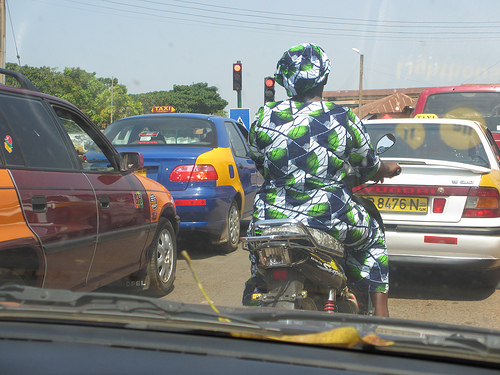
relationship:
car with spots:
[63, 93, 299, 271] [178, 126, 254, 205]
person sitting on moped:
[239, 42, 402, 318] [234, 123, 428, 321]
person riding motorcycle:
[239, 42, 402, 318] [223, 119, 430, 318]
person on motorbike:
[239, 42, 402, 318] [232, 130, 409, 326]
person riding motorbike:
[239, 42, 402, 318] [235, 123, 435, 323]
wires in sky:
[85, 2, 497, 49] [3, 3, 495, 126]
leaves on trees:
[51, 69, 234, 129] [0, 49, 239, 150]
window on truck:
[423, 93, 495, 133] [407, 76, 494, 141]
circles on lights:
[263, 72, 275, 87] [252, 68, 286, 115]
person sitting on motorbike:
[239, 42, 402, 318] [235, 123, 435, 323]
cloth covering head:
[268, 31, 341, 109] [269, 34, 343, 111]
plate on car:
[351, 174, 457, 217] [324, 109, 495, 286]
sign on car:
[123, 90, 189, 130] [92, 93, 312, 272]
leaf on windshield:
[208, 298, 396, 368] [0, 51, 446, 371]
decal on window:
[0, 131, 22, 157] [2, 84, 68, 190]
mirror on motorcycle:
[361, 129, 402, 171] [182, 150, 386, 302]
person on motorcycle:
[239, 42, 402, 318] [206, 210, 396, 319]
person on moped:
[239, 49, 459, 229] [216, 199, 375, 322]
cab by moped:
[358, 117, 499, 289] [275, 207, 377, 311]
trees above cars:
[91, 83, 145, 129] [21, 93, 495, 353]